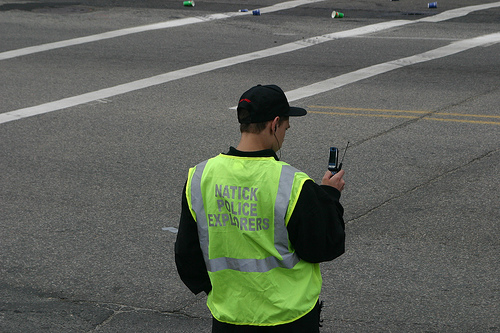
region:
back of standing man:
[178, 79, 352, 330]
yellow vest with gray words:
[190, 159, 317, 325]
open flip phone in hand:
[321, 141, 353, 183]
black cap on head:
[236, 79, 308, 129]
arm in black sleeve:
[284, 181, 346, 263]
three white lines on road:
[0, 2, 496, 126]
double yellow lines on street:
[308, 101, 496, 132]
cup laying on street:
[323, 7, 348, 29]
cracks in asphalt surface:
[43, 288, 168, 330]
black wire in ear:
[270, 127, 284, 162]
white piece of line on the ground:
[113, 79, 140, 104]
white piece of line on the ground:
[27, 99, 57, 126]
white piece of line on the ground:
[89, 90, 98, 99]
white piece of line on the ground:
[115, 80, 137, 95]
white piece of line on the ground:
[324, 76, 350, 93]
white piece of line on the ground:
[355, 63, 385, 79]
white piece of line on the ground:
[338, 72, 375, 84]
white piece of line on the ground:
[378, 56, 417, 73]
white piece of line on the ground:
[345, 65, 372, 82]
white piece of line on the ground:
[330, 72, 352, 84]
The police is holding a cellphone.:
[188, 85, 349, 305]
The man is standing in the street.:
[204, 80, 366, 310]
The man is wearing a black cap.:
[218, 67, 311, 123]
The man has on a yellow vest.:
[165, 145, 304, 330]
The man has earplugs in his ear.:
[271, 118, 287, 155]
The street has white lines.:
[58, 22, 230, 110]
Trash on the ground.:
[233, 6, 364, 46]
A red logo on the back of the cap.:
[235, 88, 255, 104]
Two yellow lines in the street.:
[303, 96, 478, 143]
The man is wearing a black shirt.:
[274, 176, 354, 266]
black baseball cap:
[233, 80, 309, 119]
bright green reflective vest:
[189, 151, 321, 323]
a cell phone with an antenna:
[323, 135, 353, 180]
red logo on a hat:
[235, 93, 255, 107]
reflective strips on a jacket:
[187, 153, 302, 274]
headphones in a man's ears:
[267, 125, 285, 144]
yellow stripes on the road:
[312, 93, 499, 140]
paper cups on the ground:
[177, 2, 455, 20]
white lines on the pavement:
[3, 5, 498, 128]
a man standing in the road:
[171, 79, 350, 331]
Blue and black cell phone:
[319, 138, 356, 191]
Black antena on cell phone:
[341, 138, 347, 170]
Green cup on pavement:
[326, 3, 351, 28]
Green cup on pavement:
[178, 0, 201, 10]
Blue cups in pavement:
[235, 2, 267, 22]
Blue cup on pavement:
[422, 1, 447, 13]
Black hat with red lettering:
[224, 68, 306, 134]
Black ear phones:
[266, 119, 291, 156]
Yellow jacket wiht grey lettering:
[187, 175, 291, 247]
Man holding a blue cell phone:
[141, 73, 368, 328]